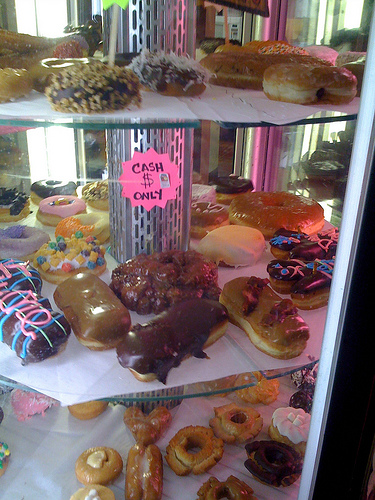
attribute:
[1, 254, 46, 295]
pastry — dark brown, frosted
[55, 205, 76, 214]
icing — pink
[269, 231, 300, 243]
icing — pink, blue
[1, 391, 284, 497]
paper — white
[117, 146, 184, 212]
sign — pink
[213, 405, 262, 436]
donut — displayed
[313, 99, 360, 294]
pole — silver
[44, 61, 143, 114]
doughnut — chocolate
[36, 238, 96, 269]
donut — glazed, tan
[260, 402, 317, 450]
donut — displayed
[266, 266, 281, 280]
frosting — brown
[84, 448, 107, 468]
filling — cream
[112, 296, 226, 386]
frosting — chocolate